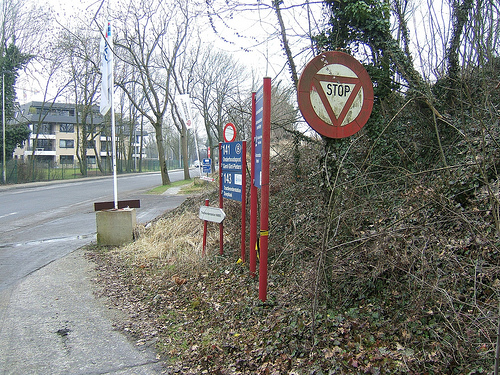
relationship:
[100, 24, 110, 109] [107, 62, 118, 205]
flag on a pole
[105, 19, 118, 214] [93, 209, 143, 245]
flag pole in cement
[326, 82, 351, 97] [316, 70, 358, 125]
word on triangle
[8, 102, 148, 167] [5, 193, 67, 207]
building on side of road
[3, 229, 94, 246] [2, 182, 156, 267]
puddle on pavement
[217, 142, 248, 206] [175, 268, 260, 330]
board in grass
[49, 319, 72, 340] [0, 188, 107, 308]
mark in road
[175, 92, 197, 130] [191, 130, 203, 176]
banner flag on pole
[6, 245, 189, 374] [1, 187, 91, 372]
shoulder at curve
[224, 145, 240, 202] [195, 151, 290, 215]
text on board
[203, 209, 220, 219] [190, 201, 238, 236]
letters on sign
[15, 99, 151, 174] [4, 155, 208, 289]
building on far side of road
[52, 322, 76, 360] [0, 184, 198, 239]
mark in road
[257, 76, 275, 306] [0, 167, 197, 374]
pole by pavement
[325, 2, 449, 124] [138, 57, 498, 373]
tree on hill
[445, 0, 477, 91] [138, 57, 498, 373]
tree on hill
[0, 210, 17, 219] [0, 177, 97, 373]
marking in road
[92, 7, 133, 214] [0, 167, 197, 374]
flag pole next to pavement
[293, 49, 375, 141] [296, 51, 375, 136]
signs on sign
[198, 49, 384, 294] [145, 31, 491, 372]
signs on hillside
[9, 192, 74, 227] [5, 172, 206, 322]
portion of road